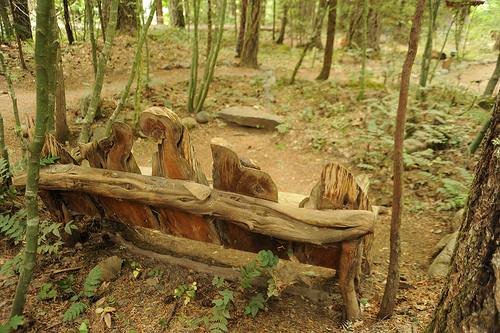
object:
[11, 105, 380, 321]
bench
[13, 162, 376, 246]
log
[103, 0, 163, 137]
stem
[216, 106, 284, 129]
rock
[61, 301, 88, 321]
leaves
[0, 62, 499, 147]
trail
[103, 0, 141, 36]
tree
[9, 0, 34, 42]
tree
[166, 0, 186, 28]
tree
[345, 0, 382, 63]
tree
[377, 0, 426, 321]
trunk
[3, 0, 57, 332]
trunk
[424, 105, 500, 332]
trunk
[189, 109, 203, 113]
root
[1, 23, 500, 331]
ground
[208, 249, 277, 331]
plant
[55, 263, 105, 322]
plant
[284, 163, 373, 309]
plank